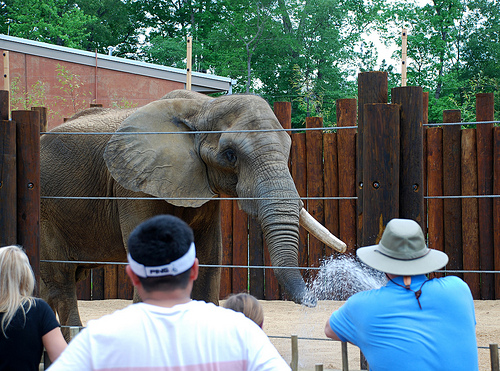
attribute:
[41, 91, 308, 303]
elephant — walking, spitting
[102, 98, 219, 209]
ear — large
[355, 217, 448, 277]
hat — khaki, olive green, gray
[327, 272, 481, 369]
t-shirt — blue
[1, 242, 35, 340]
hair — blonde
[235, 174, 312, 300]
trunk — gray, long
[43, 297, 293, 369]
shirt — white, blue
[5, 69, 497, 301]
fence — wooden, brown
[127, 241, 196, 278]
head band — white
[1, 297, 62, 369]
t-shirt — black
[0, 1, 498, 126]
trees — green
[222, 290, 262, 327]
hair — blonde